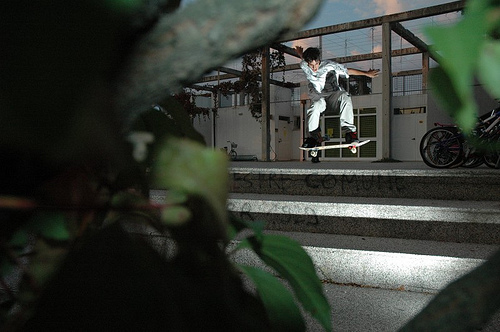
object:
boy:
[292, 41, 379, 145]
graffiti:
[231, 165, 405, 192]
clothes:
[295, 58, 350, 133]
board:
[298, 137, 372, 157]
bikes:
[418, 99, 500, 168]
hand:
[294, 46, 305, 59]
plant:
[1, 0, 334, 330]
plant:
[430, 1, 497, 133]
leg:
[305, 95, 326, 139]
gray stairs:
[218, 167, 499, 294]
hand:
[368, 68, 382, 80]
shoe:
[346, 133, 356, 146]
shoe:
[302, 136, 322, 148]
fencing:
[249, 3, 399, 54]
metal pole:
[379, 20, 394, 161]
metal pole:
[259, 40, 272, 162]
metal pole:
[421, 52, 431, 93]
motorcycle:
[416, 95, 498, 170]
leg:
[330, 92, 356, 130]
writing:
[291, 169, 404, 192]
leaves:
[132, 119, 336, 331]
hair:
[300, 45, 323, 62]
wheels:
[308, 150, 320, 156]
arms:
[342, 65, 368, 76]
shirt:
[298, 59, 352, 98]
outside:
[0, 0, 499, 330]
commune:
[279, 175, 410, 192]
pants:
[303, 88, 358, 133]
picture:
[2, 0, 496, 327]